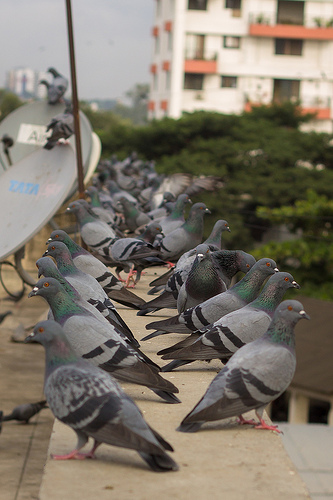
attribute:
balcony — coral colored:
[183, 56, 218, 73]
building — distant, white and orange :
[144, 1, 331, 123]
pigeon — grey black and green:
[141, 259, 281, 341]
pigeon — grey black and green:
[153, 271, 301, 373]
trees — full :
[183, 109, 328, 226]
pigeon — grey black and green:
[183, 292, 318, 436]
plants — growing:
[254, 12, 331, 31]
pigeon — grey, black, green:
[43, 244, 140, 359]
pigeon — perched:
[43, 105, 73, 147]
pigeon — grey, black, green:
[43, 287, 191, 409]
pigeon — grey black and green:
[174, 243, 227, 314]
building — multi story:
[144, 0, 330, 141]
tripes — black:
[57, 391, 127, 440]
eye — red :
[287, 277, 292, 283]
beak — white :
[291, 280, 298, 284]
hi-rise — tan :
[146, 4, 320, 128]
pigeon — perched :
[178, 298, 303, 431]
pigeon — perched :
[24, 318, 177, 469]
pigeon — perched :
[29, 273, 180, 401]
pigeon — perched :
[161, 272, 294, 370]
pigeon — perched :
[35, 253, 128, 349]